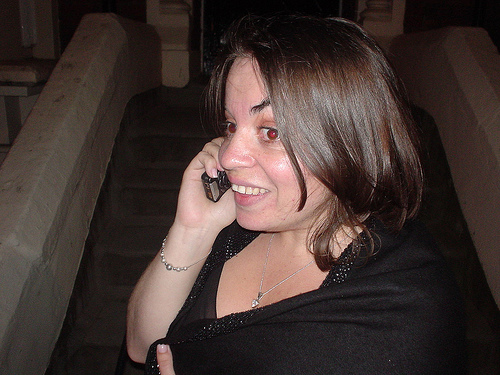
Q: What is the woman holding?
A: A phone.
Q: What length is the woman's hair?
A: Shoulder.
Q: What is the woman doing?
A: Talking on the phone.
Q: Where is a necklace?
A: Around woman's neck.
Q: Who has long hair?
A: The woman.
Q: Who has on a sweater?
A: A woman.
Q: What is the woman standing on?
A: Stairs.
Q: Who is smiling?
A: Woman on phone.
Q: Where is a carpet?
A: On stairs.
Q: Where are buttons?
A: On phone.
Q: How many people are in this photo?
A: One.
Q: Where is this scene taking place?
A: On a walkway.